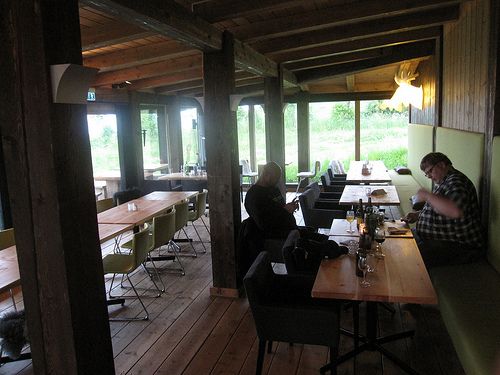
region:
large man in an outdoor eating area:
[388, 143, 495, 285]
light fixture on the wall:
[371, 67, 452, 125]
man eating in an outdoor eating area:
[244, 160, 316, 266]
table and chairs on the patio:
[108, 182, 212, 290]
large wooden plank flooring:
[155, 305, 230, 365]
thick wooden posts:
[195, 53, 241, 307]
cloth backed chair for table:
[239, 242, 346, 367]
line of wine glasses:
[346, 190, 386, 290]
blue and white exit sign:
[83, 89, 98, 105]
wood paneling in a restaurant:
[444, 72, 479, 125]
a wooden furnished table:
[310, 216, 438, 306]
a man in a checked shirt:
[406, 150, 487, 280]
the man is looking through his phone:
[246, 153, 339, 258]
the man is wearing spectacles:
[400, 140, 497, 286]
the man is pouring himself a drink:
[391, 140, 484, 269]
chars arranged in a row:
[109, 188, 214, 323]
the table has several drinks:
[323, 199, 438, 314]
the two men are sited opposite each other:
[228, 141, 481, 295]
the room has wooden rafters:
[0, 1, 491, 138]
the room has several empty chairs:
[19, 144, 486, 374]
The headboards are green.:
[407, 125, 427, 160]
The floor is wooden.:
[140, 300, 240, 365]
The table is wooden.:
[302, 192, 439, 314]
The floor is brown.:
[151, 316, 213, 361]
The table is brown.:
[348, 231, 426, 301]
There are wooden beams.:
[184, 43, 254, 303]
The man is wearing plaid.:
[401, 145, 475, 255]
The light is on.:
[370, 67, 435, 127]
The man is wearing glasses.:
[411, 162, 456, 182]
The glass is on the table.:
[348, 245, 379, 289]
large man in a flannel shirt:
[395, 145, 483, 262]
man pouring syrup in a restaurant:
[393, 145, 483, 282]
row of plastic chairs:
[101, 197, 211, 300]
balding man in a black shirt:
[235, 150, 318, 269]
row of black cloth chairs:
[300, 167, 349, 222]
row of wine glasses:
[343, 189, 384, 283]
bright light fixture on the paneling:
[382, 82, 424, 130]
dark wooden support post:
[16, 112, 126, 329]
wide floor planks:
[126, 317, 241, 357]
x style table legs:
[318, 306, 429, 373]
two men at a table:
[213, 122, 493, 316]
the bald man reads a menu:
[217, 122, 336, 274]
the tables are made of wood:
[224, 124, 497, 336]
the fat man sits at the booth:
[359, 118, 487, 281]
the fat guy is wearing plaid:
[378, 117, 494, 297]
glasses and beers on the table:
[327, 174, 408, 310]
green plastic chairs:
[86, 209, 205, 331]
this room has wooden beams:
[143, 10, 394, 320]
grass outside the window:
[231, 107, 426, 217]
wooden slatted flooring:
[169, 309, 243, 367]